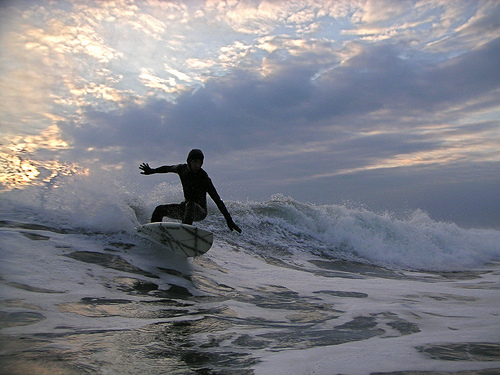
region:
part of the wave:
[397, 289, 415, 302]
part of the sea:
[298, 263, 322, 286]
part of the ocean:
[256, 281, 280, 318]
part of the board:
[189, 220, 197, 236]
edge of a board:
[163, 220, 170, 230]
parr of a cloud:
[323, 135, 337, 146]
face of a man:
[183, 140, 208, 177]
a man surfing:
[79, 93, 386, 318]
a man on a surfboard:
[64, 84, 405, 372]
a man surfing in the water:
[52, 104, 373, 371]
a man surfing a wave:
[61, 82, 404, 354]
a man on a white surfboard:
[122, 120, 282, 297]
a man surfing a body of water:
[72, 71, 349, 371]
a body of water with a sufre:
[44, 90, 354, 362]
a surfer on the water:
[54, 89, 422, 371]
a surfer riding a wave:
[16, 100, 389, 370]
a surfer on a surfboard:
[99, 128, 379, 329]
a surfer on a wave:
[129, 139, 247, 261]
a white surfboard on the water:
[128, 216, 223, 263]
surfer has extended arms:
[130, 135, 241, 241]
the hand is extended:
[134, 155, 159, 178]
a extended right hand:
[127, 153, 194, 179]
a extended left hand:
[205, 172, 252, 238]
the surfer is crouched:
[127, 139, 252, 242]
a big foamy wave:
[239, 189, 499, 277]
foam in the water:
[13, 263, 492, 365]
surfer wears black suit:
[131, 137, 249, 242]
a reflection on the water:
[113, 246, 259, 373]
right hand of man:
[136, 146, 191, 183]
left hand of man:
[194, 156, 247, 241]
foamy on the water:
[10, 226, 495, 373]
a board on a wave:
[128, 213, 218, 264]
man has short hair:
[123, 142, 251, 257]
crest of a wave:
[0, 160, 492, 274]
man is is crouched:
[126, 142, 251, 237]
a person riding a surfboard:
[120, 133, 235, 260]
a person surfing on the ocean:
[119, 140, 251, 268]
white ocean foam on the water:
[242, 269, 454, 371]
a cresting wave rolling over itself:
[250, 190, 435, 266]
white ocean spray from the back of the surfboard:
[42, 162, 138, 232]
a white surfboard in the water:
[136, 225, 212, 269]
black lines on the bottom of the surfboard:
[156, 229, 209, 257]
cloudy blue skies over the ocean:
[41, 10, 250, 118]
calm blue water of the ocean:
[71, 326, 186, 373]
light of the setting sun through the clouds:
[12, 129, 84, 194]